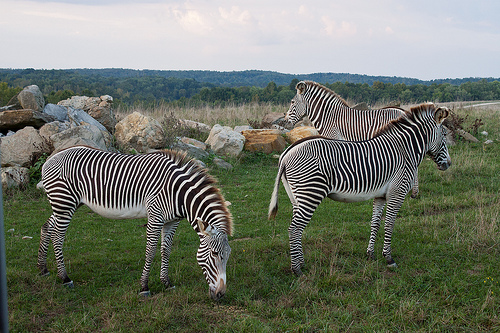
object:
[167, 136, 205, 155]
rock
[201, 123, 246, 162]
rock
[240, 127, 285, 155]
rock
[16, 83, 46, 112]
rock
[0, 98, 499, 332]
field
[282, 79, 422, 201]
zebras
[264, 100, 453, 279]
zebras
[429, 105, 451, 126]
ears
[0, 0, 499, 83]
clouds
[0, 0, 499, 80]
sky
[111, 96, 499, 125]
brown grass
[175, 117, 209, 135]
rocks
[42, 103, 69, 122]
rock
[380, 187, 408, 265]
legs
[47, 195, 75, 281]
legs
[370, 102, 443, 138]
mane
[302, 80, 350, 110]
mane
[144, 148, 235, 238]
mane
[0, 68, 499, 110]
mountains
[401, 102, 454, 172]
head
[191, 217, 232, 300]
head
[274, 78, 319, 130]
head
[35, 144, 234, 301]
zebra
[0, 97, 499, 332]
grass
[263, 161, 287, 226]
tail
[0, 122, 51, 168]
large rock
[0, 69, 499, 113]
trees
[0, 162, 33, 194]
rock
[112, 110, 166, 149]
rock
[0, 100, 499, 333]
ground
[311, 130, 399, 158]
back